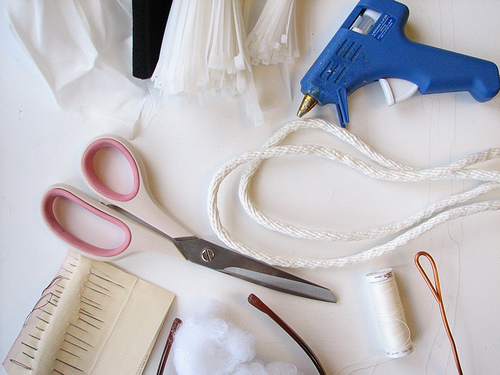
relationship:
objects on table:
[37, 133, 338, 304] [1, 93, 35, 276]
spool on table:
[364, 267, 413, 359] [1, 93, 35, 276]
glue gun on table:
[296, 2, 500, 127] [1, 93, 35, 276]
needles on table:
[4, 252, 182, 373] [1, 93, 35, 276]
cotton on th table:
[167, 315, 306, 374] [1, 93, 35, 276]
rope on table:
[198, 107, 500, 276] [1, 93, 35, 276]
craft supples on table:
[68, 9, 464, 345] [1, 93, 35, 276]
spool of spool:
[384, 288, 398, 330] [364, 267, 413, 359]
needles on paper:
[4, 252, 182, 373] [117, 303, 150, 337]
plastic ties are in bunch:
[159, 2, 307, 110] [159, 40, 295, 81]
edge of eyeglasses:
[246, 294, 265, 307] [245, 291, 333, 372]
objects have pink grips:
[37, 133, 338, 304] [38, 132, 189, 271]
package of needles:
[46, 246, 179, 328] [4, 252, 182, 373]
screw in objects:
[199, 249, 217, 260] [37, 133, 338, 304]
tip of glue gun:
[293, 95, 316, 119] [296, 2, 500, 127]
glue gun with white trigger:
[296, 2, 500, 127] [375, 76, 425, 104]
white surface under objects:
[168, 109, 225, 187] [46, 95, 431, 300]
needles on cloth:
[4, 252, 182, 373] [1, 1, 158, 127]